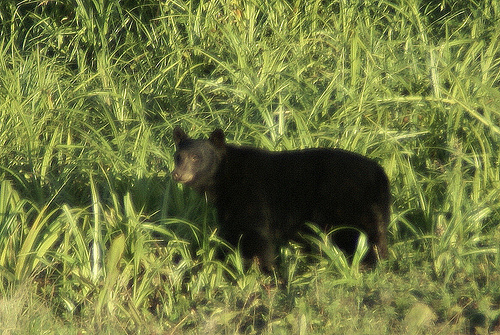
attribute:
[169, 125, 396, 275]
bear — large, looking, dark, black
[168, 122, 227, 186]
head — black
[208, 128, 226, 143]
ear — brown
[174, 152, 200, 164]
eyes — black, dark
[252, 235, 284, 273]
leg — black, dark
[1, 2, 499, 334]
grass — vivid, dark, sunny, bright, messy, patch, green, tall, high, area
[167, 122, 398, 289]
animal — wild